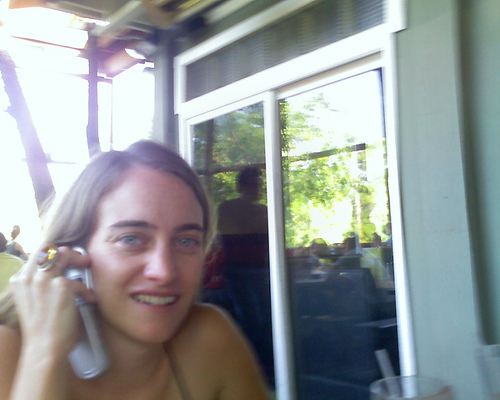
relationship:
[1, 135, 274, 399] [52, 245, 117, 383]
woman holding phone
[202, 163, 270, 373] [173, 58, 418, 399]
reflection on door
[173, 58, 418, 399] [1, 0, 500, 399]
door in background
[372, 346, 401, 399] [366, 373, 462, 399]
straw in drink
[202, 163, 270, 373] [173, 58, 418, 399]
reflection in door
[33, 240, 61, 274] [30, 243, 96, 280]
ring on finger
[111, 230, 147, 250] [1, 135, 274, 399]
eye on woman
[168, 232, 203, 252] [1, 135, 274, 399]
eye on woman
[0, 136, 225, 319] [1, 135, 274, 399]
hair on woman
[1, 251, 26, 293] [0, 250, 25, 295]
person in shirt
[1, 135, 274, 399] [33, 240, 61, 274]
woman wearing ring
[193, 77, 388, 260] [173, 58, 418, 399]
trees in door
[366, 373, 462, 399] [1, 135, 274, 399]
drink near woman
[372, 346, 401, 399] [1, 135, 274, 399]
straw near woman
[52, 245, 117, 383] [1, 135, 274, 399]
phone on woman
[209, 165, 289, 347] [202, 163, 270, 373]
man in reflection